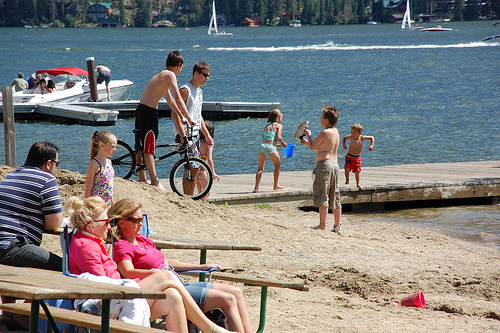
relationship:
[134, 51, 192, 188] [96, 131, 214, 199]
man on a bicycle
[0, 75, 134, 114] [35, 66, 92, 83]
boat with red canopy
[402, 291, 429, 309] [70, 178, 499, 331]
pail in sand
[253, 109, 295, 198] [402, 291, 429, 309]
girl holding pail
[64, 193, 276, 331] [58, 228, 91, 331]
lady sitting in a chair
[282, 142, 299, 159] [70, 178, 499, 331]
bucket in sand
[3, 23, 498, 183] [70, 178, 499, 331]
beach with sand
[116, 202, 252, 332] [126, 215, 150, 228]
woman wearing sunglasses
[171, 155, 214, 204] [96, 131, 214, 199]
wheel of bicycle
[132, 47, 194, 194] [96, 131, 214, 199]
boy riding bicycle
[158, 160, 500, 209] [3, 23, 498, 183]
boardwalk over water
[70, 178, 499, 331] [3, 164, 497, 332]
sand on beach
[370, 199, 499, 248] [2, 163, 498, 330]
water near sand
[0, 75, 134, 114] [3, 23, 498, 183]
boat on water